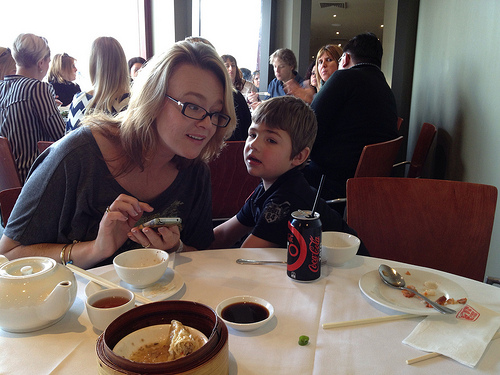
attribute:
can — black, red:
[287, 209, 322, 282]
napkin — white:
[408, 329, 470, 369]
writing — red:
[456, 304, 485, 326]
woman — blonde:
[51, 34, 155, 134]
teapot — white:
[0, 255, 83, 332]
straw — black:
[294, 170, 336, 218]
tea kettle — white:
[0, 256, 76, 334]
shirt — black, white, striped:
[1, 74, 69, 175]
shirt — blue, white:
[69, 79, 132, 128]